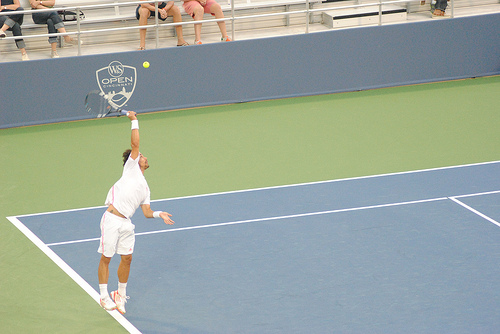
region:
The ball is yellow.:
[138, 54, 148, 75]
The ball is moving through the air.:
[125, 53, 157, 80]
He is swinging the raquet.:
[81, 89, 179, 323]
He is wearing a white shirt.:
[93, 149, 163, 216]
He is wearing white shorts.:
[87, 208, 138, 257]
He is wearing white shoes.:
[90, 278, 132, 313]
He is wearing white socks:
[90, 273, 138, 313]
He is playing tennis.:
[61, 40, 182, 313]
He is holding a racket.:
[80, 82, 140, 137]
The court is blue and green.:
[7, 95, 479, 332]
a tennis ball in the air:
[141, 59, 150, 69]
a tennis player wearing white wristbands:
[98, 110, 175, 313]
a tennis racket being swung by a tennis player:
[82, 90, 132, 120]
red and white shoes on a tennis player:
[98, 290, 130, 313]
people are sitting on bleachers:
[0, 0, 497, 60]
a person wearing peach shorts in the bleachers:
[181, 0, 236, 44]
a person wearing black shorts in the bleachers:
[135, 1, 190, 48]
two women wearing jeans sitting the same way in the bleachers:
[0, 0, 83, 60]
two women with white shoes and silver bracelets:
[0, 0, 81, 57]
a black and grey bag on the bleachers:
[57, 7, 84, 23]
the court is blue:
[260, 187, 497, 294]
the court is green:
[256, 110, 407, 157]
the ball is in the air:
[145, 60, 155, 65]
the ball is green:
[140, 60, 150, 67]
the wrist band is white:
[122, 116, 142, 126]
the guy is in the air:
[95, 140, 160, 310]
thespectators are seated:
[55, 0, 245, 40]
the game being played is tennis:
[3, 1, 498, 326]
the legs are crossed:
[1, 5, 94, 54]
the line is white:
[251, 205, 324, 235]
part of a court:
[284, 211, 346, 283]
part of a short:
[101, 230, 138, 274]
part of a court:
[286, 287, 307, 315]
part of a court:
[231, 212, 263, 267]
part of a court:
[203, 172, 234, 212]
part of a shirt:
[111, 165, 138, 212]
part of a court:
[298, 269, 340, 309]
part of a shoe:
[91, 290, 123, 319]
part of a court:
[271, 238, 302, 263]